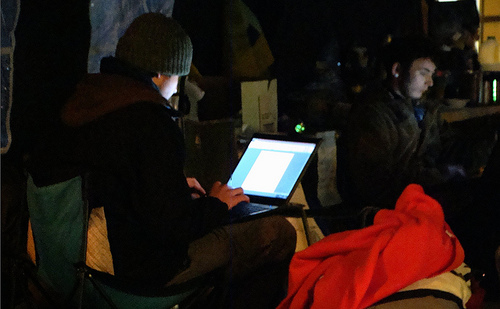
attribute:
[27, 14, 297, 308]
man — sitting, living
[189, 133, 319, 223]
laptop — open, bright, black, on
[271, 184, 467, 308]
blanket — red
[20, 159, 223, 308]
chair — green, folding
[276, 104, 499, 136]
table — cluttered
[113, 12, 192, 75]
hat — woolen, green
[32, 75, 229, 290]
coat — brown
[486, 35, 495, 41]
top — blue